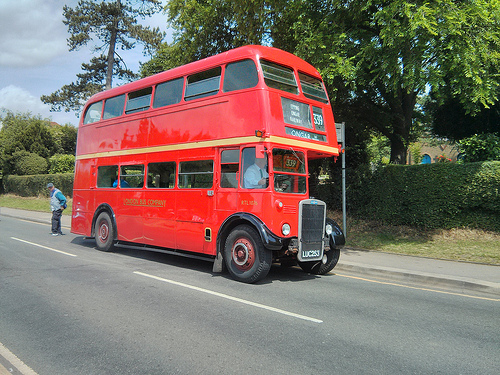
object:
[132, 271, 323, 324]
line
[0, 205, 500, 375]
road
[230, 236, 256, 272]
hubcap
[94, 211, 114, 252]
tire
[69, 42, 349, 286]
bus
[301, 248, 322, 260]
plate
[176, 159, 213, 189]
window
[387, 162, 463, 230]
bushes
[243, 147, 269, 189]
driver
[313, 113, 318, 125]
number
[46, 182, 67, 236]
man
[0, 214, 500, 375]
street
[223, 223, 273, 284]
wheel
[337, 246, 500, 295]
sidewalk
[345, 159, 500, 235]
hedge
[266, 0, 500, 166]
tree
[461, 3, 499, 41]
leaves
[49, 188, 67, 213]
shirt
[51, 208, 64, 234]
pants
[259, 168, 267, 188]
tie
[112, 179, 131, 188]
shirt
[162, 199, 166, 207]
word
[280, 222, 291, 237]
headlight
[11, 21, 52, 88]
cloud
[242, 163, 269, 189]
shirt